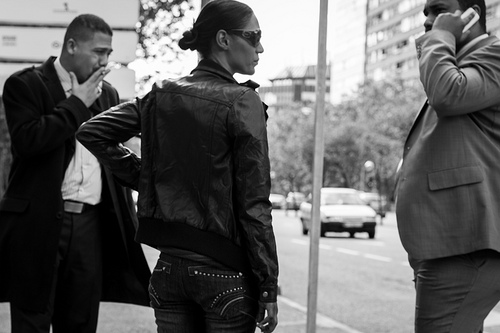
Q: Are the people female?
A: No, they are both male and female.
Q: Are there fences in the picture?
A: No, there are no fences.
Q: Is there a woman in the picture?
A: Yes, there is a woman.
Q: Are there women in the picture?
A: Yes, there is a woman.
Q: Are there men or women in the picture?
A: Yes, there is a woman.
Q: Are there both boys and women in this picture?
A: No, there is a woman but no boys.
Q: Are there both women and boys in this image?
A: No, there is a woman but no boys.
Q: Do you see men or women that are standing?
A: Yes, the woman is standing.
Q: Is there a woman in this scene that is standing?
A: Yes, there is a woman that is standing.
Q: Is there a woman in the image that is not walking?
A: Yes, there is a woman that is standing.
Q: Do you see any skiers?
A: No, there are no skiers.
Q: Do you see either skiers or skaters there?
A: No, there are no skiers or skaters.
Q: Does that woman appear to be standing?
A: Yes, the woman is standing.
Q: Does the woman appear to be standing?
A: Yes, the woman is standing.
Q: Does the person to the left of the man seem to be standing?
A: Yes, the woman is standing.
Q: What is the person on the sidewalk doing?
A: The woman is standing.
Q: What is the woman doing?
A: The woman is standing.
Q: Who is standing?
A: The woman is standing.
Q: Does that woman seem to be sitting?
A: No, the woman is standing.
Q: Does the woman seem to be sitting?
A: No, the woman is standing.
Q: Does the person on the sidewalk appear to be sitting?
A: No, the woman is standing.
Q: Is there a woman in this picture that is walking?
A: No, there is a woman but she is standing.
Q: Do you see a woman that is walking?
A: No, there is a woman but she is standing.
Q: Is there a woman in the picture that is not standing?
A: No, there is a woman but she is standing.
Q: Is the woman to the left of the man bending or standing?
A: The woman is standing.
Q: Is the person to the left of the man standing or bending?
A: The woman is standing.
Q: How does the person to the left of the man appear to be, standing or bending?
A: The woman is standing.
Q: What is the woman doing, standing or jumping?
A: The woman is standing.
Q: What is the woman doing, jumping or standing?
A: The woman is standing.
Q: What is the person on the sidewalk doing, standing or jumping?
A: The woman is standing.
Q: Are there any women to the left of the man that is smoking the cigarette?
A: Yes, there is a woman to the left of the man.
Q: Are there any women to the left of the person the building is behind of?
A: Yes, there is a woman to the left of the man.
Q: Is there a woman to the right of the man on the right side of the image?
A: No, the woman is to the left of the man.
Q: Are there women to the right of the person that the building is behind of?
A: No, the woman is to the left of the man.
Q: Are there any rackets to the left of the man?
A: No, there is a woman to the left of the man.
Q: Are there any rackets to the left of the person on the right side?
A: No, there is a woman to the left of the man.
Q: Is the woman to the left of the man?
A: Yes, the woman is to the left of the man.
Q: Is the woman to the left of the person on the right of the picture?
A: Yes, the woman is to the left of the man.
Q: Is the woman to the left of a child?
A: No, the woman is to the left of the man.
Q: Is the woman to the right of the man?
A: No, the woman is to the left of the man.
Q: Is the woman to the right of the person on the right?
A: No, the woman is to the left of the man.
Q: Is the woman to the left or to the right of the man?
A: The woman is to the left of the man.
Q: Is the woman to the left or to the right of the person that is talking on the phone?
A: The woman is to the left of the man.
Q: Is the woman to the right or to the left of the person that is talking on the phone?
A: The woman is to the left of the man.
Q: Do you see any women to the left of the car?
A: Yes, there is a woman to the left of the car.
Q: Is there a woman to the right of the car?
A: No, the woman is to the left of the car.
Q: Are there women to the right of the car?
A: No, the woman is to the left of the car.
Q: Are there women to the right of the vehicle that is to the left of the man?
A: No, the woman is to the left of the car.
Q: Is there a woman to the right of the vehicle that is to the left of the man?
A: No, the woman is to the left of the car.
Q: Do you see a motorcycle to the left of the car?
A: No, there is a woman to the left of the car.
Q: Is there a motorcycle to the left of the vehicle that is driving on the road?
A: No, there is a woman to the left of the car.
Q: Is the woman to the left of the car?
A: Yes, the woman is to the left of the car.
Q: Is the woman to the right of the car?
A: No, the woman is to the left of the car.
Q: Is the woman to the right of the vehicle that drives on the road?
A: No, the woman is to the left of the car.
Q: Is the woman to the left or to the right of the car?
A: The woman is to the left of the car.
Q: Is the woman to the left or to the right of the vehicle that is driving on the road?
A: The woman is to the left of the car.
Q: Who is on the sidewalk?
A: The woman is on the sidewalk.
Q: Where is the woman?
A: The woman is on the sidewalk.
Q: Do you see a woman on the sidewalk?
A: Yes, there is a woman on the sidewalk.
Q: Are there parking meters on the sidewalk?
A: No, there is a woman on the sidewalk.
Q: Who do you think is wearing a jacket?
A: The woman is wearing a jacket.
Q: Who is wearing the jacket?
A: The woman is wearing a jacket.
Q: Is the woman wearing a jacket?
A: Yes, the woman is wearing a jacket.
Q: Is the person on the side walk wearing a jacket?
A: Yes, the woman is wearing a jacket.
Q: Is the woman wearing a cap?
A: No, the woman is wearing a jacket.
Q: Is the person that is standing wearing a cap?
A: No, the woman is wearing a jacket.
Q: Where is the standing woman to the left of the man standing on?
A: The woman is standing on the side walk.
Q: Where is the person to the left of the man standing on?
A: The woman is standing on the side walk.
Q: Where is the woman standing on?
A: The woman is standing on the side walk.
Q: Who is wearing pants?
A: The woman is wearing pants.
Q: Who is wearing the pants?
A: The woman is wearing pants.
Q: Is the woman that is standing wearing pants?
A: Yes, the woman is wearing pants.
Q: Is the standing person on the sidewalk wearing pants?
A: Yes, the woman is wearing pants.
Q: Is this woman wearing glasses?
A: No, the woman is wearing pants.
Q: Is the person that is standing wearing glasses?
A: No, the woman is wearing pants.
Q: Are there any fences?
A: No, there are no fences.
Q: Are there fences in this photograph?
A: No, there are no fences.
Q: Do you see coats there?
A: Yes, there is a coat.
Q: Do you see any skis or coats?
A: Yes, there is a coat.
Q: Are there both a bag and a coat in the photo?
A: No, there is a coat but no bags.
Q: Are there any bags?
A: No, there are no bags.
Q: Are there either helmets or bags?
A: No, there are no bags or helmets.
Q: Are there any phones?
A: Yes, there is a phone.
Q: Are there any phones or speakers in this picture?
A: Yes, there is a phone.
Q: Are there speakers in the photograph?
A: No, there are no speakers.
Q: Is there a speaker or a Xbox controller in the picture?
A: No, there are no speakers or Xbox controllers.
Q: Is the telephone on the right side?
A: Yes, the telephone is on the right of the image.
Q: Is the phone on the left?
A: No, the phone is on the right of the image.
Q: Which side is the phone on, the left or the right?
A: The phone is on the right of the image.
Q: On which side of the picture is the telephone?
A: The telephone is on the right of the image.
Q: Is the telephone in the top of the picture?
A: Yes, the telephone is in the top of the image.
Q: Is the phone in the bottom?
A: No, the phone is in the top of the image.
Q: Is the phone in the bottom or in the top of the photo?
A: The phone is in the top of the image.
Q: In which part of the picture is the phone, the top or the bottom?
A: The phone is in the top of the image.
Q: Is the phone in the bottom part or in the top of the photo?
A: The phone is in the top of the image.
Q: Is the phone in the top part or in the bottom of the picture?
A: The phone is in the top of the image.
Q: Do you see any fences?
A: No, there are no fences.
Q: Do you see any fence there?
A: No, there are no fences.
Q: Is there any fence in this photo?
A: No, there are no fences.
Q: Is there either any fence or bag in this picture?
A: No, there are no fences or bags.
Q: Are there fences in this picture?
A: No, there are no fences.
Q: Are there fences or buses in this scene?
A: No, there are no fences or buses.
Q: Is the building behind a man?
A: Yes, the building is behind a man.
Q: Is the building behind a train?
A: No, the building is behind a man.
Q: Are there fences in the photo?
A: No, there are no fences.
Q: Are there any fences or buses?
A: No, there are no fences or buses.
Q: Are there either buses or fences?
A: No, there are no fences or buses.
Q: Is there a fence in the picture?
A: No, there are no fences.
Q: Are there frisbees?
A: No, there are no frisbees.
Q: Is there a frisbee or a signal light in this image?
A: No, there are no frisbees or traffic lights.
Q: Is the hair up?
A: Yes, the hair is up.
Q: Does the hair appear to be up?
A: Yes, the hair is up.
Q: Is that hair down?
A: No, the hair is up.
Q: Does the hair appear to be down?
A: No, the hair is up.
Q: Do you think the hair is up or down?
A: The hair is up.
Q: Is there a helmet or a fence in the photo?
A: No, there are no fences or helmets.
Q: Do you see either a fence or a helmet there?
A: No, there are no fences or helmets.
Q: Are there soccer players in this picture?
A: No, there are no soccer players.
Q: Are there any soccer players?
A: No, there are no soccer players.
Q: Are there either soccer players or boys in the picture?
A: No, there are no soccer players or boys.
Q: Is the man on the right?
A: Yes, the man is on the right of the image.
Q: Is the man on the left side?
A: No, the man is on the right of the image.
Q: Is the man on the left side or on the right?
A: The man is on the right of the image.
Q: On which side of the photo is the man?
A: The man is on the right of the image.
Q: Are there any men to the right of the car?
A: Yes, there is a man to the right of the car.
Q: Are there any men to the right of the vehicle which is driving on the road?
A: Yes, there is a man to the right of the car.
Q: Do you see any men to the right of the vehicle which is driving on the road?
A: Yes, there is a man to the right of the car.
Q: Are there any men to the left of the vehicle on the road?
A: No, the man is to the right of the car.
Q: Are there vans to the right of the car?
A: No, there is a man to the right of the car.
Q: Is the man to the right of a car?
A: Yes, the man is to the right of a car.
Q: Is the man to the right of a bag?
A: No, the man is to the right of a car.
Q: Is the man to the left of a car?
A: No, the man is to the right of a car.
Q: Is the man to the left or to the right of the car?
A: The man is to the right of the car.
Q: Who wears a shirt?
A: The man wears a shirt.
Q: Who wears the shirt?
A: The man wears a shirt.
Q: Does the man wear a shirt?
A: Yes, the man wears a shirt.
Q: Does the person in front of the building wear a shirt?
A: Yes, the man wears a shirt.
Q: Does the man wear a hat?
A: No, the man wears a shirt.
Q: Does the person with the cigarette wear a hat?
A: No, the man wears a shirt.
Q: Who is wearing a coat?
A: The man is wearing a coat.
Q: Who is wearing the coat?
A: The man is wearing a coat.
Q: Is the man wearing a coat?
A: Yes, the man is wearing a coat.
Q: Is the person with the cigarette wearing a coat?
A: Yes, the man is wearing a coat.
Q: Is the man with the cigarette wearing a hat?
A: No, the man is wearing a coat.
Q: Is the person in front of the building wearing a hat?
A: No, the man is wearing a coat.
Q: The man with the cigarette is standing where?
A: The man is standing on the sidewalk.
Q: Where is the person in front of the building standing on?
A: The man is standing on the sidewalk.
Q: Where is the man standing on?
A: The man is standing on the sidewalk.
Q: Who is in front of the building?
A: The man is in front of the building.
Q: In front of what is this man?
A: The man is in front of the building.